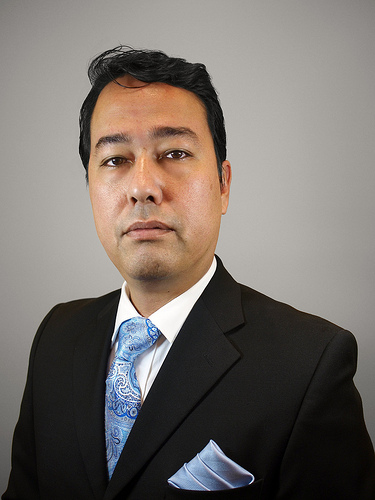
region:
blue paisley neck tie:
[104, 317, 161, 479]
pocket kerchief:
[168, 439, 254, 490]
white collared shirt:
[105, 257, 216, 445]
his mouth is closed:
[118, 219, 174, 240]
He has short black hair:
[78, 44, 228, 190]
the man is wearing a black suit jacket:
[0, 249, 373, 499]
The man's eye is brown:
[158, 145, 196, 162]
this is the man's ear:
[221, 159, 232, 214]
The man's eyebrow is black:
[150, 124, 200, 139]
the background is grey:
[0, 0, 374, 499]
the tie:
[117, 326, 143, 372]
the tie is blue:
[115, 332, 140, 396]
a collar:
[162, 308, 177, 327]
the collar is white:
[161, 308, 182, 330]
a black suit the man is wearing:
[240, 370, 337, 445]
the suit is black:
[240, 362, 316, 428]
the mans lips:
[115, 218, 170, 238]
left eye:
[162, 146, 196, 161]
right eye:
[101, 153, 126, 168]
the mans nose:
[129, 167, 162, 200]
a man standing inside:
[31, 25, 295, 284]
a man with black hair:
[35, 36, 299, 309]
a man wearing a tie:
[8, 67, 296, 490]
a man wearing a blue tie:
[16, 132, 358, 498]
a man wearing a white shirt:
[22, 178, 302, 493]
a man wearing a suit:
[53, 223, 343, 498]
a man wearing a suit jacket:
[28, 222, 324, 495]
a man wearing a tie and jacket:
[3, 243, 298, 495]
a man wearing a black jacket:
[32, 255, 365, 466]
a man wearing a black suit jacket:
[51, 243, 367, 409]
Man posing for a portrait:
[53, 50, 305, 324]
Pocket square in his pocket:
[168, 413, 237, 495]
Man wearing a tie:
[90, 314, 189, 447]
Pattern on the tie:
[100, 348, 136, 461]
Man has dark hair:
[69, 43, 238, 172]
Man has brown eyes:
[92, 127, 191, 194]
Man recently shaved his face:
[81, 157, 236, 349]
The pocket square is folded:
[162, 443, 252, 497]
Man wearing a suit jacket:
[32, 246, 363, 477]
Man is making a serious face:
[71, 113, 263, 330]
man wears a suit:
[8, 35, 369, 498]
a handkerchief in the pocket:
[163, 435, 260, 498]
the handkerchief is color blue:
[162, 437, 257, 492]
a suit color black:
[3, 267, 368, 498]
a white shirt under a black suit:
[7, 267, 373, 497]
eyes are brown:
[93, 143, 191, 169]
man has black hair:
[38, 31, 278, 367]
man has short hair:
[46, 38, 280, 343]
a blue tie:
[96, 312, 161, 481]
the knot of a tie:
[110, 313, 160, 365]